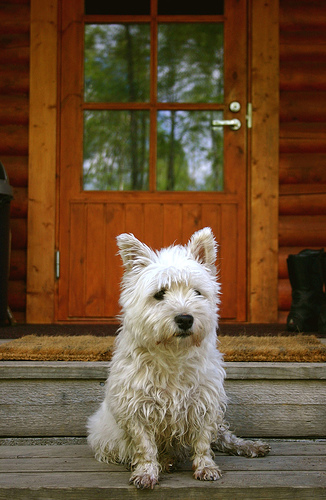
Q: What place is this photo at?
A: It is at the porch.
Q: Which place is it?
A: It is a porch.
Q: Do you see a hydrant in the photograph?
A: No, there are no fire hydrants.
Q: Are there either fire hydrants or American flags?
A: No, there are no fire hydrants or American flags.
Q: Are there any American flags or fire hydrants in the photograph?
A: No, there are no fire hydrants or American flags.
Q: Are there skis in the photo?
A: No, there are no skis.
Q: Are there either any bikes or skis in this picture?
A: No, there are no skis or bikes.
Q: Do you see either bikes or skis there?
A: No, there are no skis or bikes.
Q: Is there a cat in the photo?
A: No, there are no cats.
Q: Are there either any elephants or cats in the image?
A: No, there are no cats or elephants.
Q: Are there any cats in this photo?
A: No, there are no cats.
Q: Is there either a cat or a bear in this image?
A: No, there are no cats or bears.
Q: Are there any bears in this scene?
A: No, there are no bears.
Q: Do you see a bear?
A: No, there are no bears.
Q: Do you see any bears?
A: No, there are no bears.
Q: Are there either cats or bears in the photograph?
A: No, there are no bears or cats.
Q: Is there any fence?
A: No, there are no fences.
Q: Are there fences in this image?
A: No, there are no fences.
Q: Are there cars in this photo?
A: No, there are no cars.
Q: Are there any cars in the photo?
A: No, there are no cars.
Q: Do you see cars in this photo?
A: No, there are no cars.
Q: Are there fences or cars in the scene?
A: No, there are no cars or fences.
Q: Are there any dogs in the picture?
A: Yes, there is a dog.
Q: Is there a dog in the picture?
A: Yes, there is a dog.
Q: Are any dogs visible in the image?
A: Yes, there is a dog.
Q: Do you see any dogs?
A: Yes, there is a dog.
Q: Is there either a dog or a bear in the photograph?
A: Yes, there is a dog.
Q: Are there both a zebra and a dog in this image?
A: No, there is a dog but no zebras.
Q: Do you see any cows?
A: No, there are no cows.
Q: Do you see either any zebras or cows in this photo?
A: No, there are no cows or zebras.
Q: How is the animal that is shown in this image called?
A: The animal is a dog.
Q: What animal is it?
A: The animal is a dog.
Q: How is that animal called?
A: This is a dog.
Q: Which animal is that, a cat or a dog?
A: This is a dog.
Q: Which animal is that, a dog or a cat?
A: This is a dog.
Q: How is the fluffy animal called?
A: The animal is a dog.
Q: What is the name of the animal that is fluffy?
A: The animal is a dog.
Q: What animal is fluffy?
A: The animal is a dog.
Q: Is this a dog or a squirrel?
A: This is a dog.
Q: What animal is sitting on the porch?
A: The dog is sitting on the porch.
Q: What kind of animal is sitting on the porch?
A: The animal is a dog.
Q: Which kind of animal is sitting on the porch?
A: The animal is a dog.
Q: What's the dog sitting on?
A: The dog is sitting on the porch.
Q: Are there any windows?
A: Yes, there is a window.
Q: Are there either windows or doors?
A: Yes, there is a window.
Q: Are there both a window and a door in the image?
A: Yes, there are both a window and a door.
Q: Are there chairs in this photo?
A: No, there are no chairs.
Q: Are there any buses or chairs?
A: No, there are no chairs or buses.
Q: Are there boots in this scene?
A: Yes, there are boots.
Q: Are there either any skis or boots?
A: Yes, there are boots.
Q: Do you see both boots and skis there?
A: No, there are boots but no skis.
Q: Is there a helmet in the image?
A: No, there are no helmets.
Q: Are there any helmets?
A: No, there are no helmets.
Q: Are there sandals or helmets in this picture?
A: No, there are no helmets or sandals.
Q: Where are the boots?
A: The boots are on the porch.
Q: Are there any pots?
A: No, there are no pots.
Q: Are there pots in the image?
A: No, there are no pots.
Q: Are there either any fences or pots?
A: No, there are no pots or fences.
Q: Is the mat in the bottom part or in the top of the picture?
A: The mat is in the bottom of the image.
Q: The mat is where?
A: The mat is on the porch.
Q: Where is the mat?
A: The mat is on the porch.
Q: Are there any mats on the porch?
A: Yes, there is a mat on the porch.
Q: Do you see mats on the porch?
A: Yes, there is a mat on the porch.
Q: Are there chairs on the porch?
A: No, there is a mat on the porch.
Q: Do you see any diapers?
A: No, there are no diapers.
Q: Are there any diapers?
A: No, there are no diapers.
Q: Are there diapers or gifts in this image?
A: No, there are no diapers or gifts.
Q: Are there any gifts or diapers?
A: No, there are no diapers or gifts.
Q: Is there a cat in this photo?
A: No, there are no cats.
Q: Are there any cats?
A: No, there are no cats.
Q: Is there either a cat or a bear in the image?
A: No, there are no cats or bears.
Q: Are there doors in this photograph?
A: Yes, there is a door.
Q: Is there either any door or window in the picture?
A: Yes, there is a door.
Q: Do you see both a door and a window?
A: Yes, there are both a door and a window.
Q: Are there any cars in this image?
A: No, there are no cars.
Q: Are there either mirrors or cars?
A: No, there are no cars or mirrors.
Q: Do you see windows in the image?
A: Yes, there is a window.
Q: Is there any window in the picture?
A: Yes, there is a window.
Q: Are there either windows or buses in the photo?
A: Yes, there is a window.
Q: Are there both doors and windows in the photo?
A: Yes, there are both a window and a door.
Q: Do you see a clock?
A: No, there are no clocks.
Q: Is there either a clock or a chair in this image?
A: No, there are no clocks or chairs.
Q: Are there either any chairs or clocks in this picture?
A: No, there are no clocks or chairs.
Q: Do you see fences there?
A: No, there are no fences.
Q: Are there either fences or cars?
A: No, there are no fences or cars.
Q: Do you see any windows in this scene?
A: Yes, there is a window.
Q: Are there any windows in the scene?
A: Yes, there is a window.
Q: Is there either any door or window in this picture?
A: Yes, there is a window.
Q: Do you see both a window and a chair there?
A: No, there is a window but no chairs.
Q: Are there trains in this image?
A: No, there are no trains.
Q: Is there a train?
A: No, there are no trains.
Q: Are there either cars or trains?
A: No, there are no trains or cars.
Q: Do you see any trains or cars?
A: No, there are no trains or cars.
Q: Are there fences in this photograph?
A: No, there are no fences.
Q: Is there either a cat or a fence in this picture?
A: No, there are no fences or cats.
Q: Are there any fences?
A: No, there are no fences.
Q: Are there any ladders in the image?
A: No, there are no ladders.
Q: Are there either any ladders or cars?
A: No, there are no ladders or cars.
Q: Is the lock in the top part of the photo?
A: Yes, the lock is in the top of the image.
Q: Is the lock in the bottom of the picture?
A: No, the lock is in the top of the image.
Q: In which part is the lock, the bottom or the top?
A: The lock is in the top of the image.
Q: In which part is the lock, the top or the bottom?
A: The lock is in the top of the image.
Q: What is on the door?
A: The lock is on the door.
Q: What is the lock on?
A: The lock is on the door.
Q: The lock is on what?
A: The lock is on the door.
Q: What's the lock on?
A: The lock is on the door.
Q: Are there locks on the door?
A: Yes, there is a lock on the door.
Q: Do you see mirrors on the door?
A: No, there is a lock on the door.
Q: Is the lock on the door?
A: Yes, the lock is on the door.